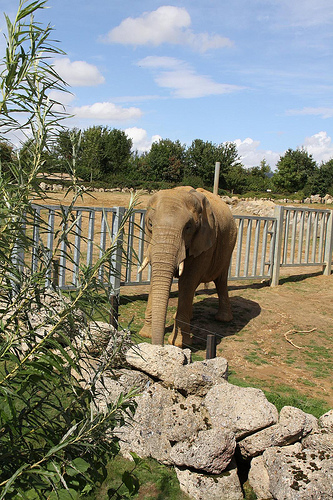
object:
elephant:
[132, 184, 237, 346]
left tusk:
[174, 262, 185, 279]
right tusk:
[136, 254, 151, 272]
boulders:
[71, 324, 332, 500]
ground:
[0, 189, 333, 401]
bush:
[0, 18, 67, 498]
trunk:
[146, 221, 182, 343]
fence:
[6, 208, 332, 302]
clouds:
[44, 7, 236, 135]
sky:
[0, 0, 333, 177]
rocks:
[0, 283, 333, 500]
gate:
[276, 210, 330, 290]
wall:
[5, 304, 333, 498]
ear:
[143, 192, 160, 234]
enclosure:
[20, 168, 332, 409]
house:
[28, 172, 84, 183]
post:
[212, 155, 220, 197]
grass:
[0, 339, 183, 500]